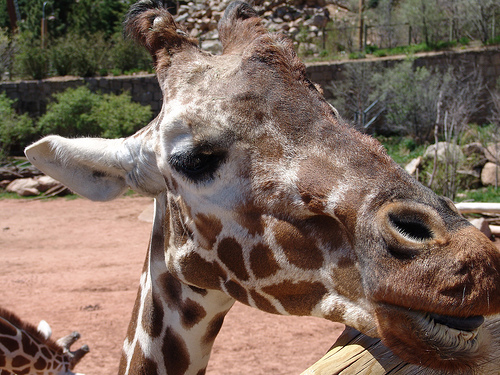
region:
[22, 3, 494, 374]
A giraffe is near the camera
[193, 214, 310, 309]
The spots are brown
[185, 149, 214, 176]
The eyeball is black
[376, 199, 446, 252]
The nose is black and brown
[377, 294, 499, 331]
The mouth is open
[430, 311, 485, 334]
The tongue is black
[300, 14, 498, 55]
There is a fence in the background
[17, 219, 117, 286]
The floor is made of dirt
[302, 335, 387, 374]
A light colored wood beam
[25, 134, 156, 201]
The ear is white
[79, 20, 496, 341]
This is a giraffe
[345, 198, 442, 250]
This is a nose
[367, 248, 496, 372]
This is a mouth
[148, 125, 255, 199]
The eye is black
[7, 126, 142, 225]
This is an ear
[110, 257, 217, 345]
This is a long neck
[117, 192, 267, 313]
The fur is spotted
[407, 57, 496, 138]
The trees have no leaves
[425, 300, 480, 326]
This is the tongue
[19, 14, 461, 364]
head of giraffe resting on fence post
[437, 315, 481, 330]
tongue of the giraffe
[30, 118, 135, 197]
white ear of giraffe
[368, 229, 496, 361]
brown mouth of giraffe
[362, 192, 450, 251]
nostril of the giraffe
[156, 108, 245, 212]
white spot around giraffe's eue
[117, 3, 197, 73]
furry horn of giraffe with black tip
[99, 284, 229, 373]
spotted neck of giraffe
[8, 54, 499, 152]
stone wall along back side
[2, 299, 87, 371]
giraffe grazing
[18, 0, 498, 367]
A giraffe's head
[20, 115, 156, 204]
A furry ear of a giraffe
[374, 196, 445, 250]
A nostril of a giraffe's nose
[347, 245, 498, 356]
The mouth of a giraffe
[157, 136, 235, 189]
A giraffe's large, brown eye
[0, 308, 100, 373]
A giraffe bending down to the ground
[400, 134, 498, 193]
A stack of gray rocks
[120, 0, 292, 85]
Two furry horns of a giraffe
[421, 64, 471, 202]
Some skinny trees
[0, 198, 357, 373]
Sandy brown soil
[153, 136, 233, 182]
Black eye of giraffe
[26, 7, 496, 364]
Closeup of giraffe's head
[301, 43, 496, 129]
Rock wall of enclosure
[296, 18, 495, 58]
Chain link fence on top of wall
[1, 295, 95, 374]
Giraffe bending down to eat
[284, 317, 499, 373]
Wooden fence rail of enclosure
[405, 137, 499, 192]
Boulders in giraffe enclosure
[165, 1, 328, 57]
Rocks on hill beyond enclosure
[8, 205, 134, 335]
Bare ground of giraffe enclosure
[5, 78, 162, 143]
Green bushes in giraffe enclosure